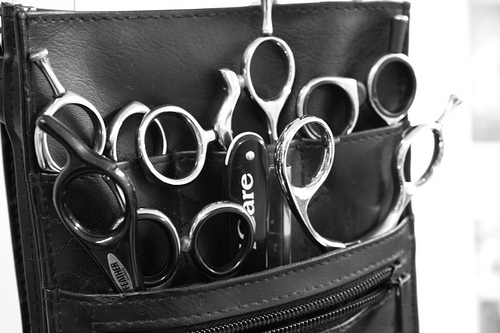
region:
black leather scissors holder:
[4, 7, 421, 331]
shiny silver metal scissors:
[273, 110, 457, 255]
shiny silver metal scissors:
[25, 42, 167, 172]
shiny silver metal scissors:
[303, 36, 420, 136]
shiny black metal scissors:
[114, 197, 247, 298]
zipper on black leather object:
[196, 256, 413, 325]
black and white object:
[220, 131, 267, 279]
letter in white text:
[240, 170, 255, 220]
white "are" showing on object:
[239, 170, 263, 212]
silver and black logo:
[103, 247, 133, 302]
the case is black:
[1, 1, 421, 331]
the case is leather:
[2, 0, 421, 332]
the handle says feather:
[105, 250, 135, 291]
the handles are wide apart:
[272, 90, 462, 250]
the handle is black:
[35, 112, 143, 289]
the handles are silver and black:
[98, 170, 251, 291]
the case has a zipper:
[92, 260, 408, 330]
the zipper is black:
[386, 253, 411, 293]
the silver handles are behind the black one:
[25, 42, 170, 167]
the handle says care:
[236, 169, 260, 252]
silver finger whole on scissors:
[34, 98, 106, 171]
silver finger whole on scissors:
[105, 100, 168, 160]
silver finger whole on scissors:
[138, 103, 206, 184]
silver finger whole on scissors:
[243, 34, 297, 106]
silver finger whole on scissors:
[297, 74, 361, 141]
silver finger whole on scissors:
[366, 50, 421, 124]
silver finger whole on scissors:
[391, 121, 447, 193]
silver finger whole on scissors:
[276, 119, 336, 198]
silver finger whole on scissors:
[191, 203, 258, 284]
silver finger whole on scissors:
[118, 207, 176, 292]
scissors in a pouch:
[41, 50, 414, 326]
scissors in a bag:
[10, 16, 443, 328]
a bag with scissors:
[32, 25, 447, 319]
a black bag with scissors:
[10, 34, 395, 322]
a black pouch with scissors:
[0, 4, 499, 325]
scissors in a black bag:
[37, 11, 414, 332]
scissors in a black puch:
[9, 11, 473, 331]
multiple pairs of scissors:
[16, 25, 496, 273]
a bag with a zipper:
[246, 258, 488, 329]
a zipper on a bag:
[215, 255, 360, 332]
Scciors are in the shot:
[25, 20, 449, 294]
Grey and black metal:
[23, 35, 469, 301]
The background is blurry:
[386, 23, 498, 331]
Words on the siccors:
[198, 144, 290, 296]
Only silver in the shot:
[24, 30, 452, 147]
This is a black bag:
[5, 4, 469, 331]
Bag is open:
[216, 276, 439, 331]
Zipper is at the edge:
[378, 257, 427, 314]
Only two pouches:
[28, 59, 448, 306]